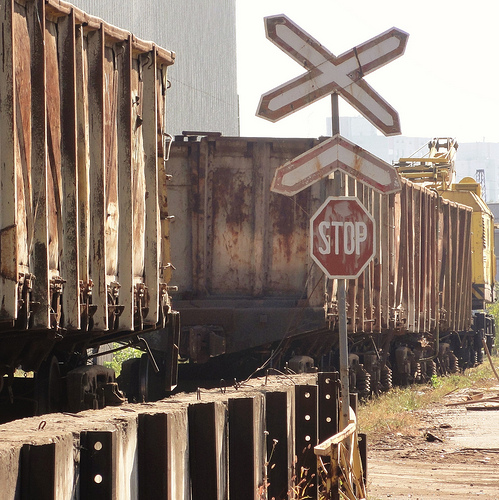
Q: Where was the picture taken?
A: At train crossing.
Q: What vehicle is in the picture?
A: Train.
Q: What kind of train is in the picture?
A: Cargo.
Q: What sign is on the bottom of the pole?
A: Stop.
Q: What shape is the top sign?
A: X.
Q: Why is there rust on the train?
A: It is old.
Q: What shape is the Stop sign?
A: Octagon.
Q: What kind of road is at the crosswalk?
A: Dirt.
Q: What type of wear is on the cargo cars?
A: Rust.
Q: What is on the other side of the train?
A: A building.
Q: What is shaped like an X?
A: The railroad sign.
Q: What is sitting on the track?
A: Train cars.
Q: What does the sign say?
A: Stop.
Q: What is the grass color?
A: Green and brown.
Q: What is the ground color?
A: Brown.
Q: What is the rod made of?
A: Iron.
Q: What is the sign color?
A: Red and white color.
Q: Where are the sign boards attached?
A: Pole.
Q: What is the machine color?
A: Yellow.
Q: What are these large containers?
A: Train cars.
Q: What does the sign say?
A: STOP.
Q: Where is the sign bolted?
A: Metal pole.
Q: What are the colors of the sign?
A: Red and white.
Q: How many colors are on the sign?
A: Two.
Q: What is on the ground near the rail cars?
A: Grass.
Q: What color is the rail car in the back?
A: Yellow.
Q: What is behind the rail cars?
A: Building.